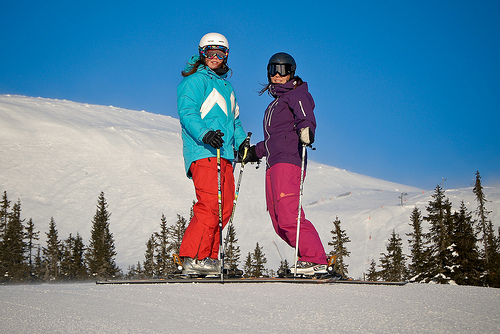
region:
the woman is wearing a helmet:
[199, 32, 228, 49]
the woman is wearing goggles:
[202, 45, 225, 59]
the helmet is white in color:
[197, 30, 225, 48]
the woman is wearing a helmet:
[266, 51, 293, 74]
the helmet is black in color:
[265, 51, 297, 78]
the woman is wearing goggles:
[266, 62, 291, 75]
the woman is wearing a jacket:
[250, 82, 315, 166]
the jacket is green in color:
[173, 65, 243, 176]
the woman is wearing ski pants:
[184, 150, 238, 266]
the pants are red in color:
[180, 155, 235, 260]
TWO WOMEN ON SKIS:
[171, 29, 342, 283]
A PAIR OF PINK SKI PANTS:
[263, 160, 331, 268]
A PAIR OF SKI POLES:
[211, 125, 256, 285]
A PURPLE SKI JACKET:
[250, 80, 319, 170]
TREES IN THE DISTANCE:
[334, 167, 498, 283]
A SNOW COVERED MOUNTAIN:
[4, 82, 178, 209]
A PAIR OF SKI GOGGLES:
[263, 60, 295, 80]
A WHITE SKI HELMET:
[194, 28, 234, 51]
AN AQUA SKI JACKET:
[174, 62, 253, 180]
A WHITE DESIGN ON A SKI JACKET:
[196, 86, 241, 123]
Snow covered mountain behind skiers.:
[11, 63, 495, 286]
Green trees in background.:
[6, 178, 497, 300]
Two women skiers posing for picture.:
[121, 10, 388, 301]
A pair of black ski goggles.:
[259, 48, 302, 89]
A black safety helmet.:
[256, 51, 313, 97]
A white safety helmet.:
[193, 28, 239, 76]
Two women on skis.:
[164, 16, 360, 293]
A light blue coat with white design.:
[173, 65, 250, 165]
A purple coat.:
[251, 79, 318, 168]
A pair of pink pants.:
[256, 155, 343, 276]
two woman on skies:
[85, 7, 392, 332]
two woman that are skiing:
[97, 4, 448, 330]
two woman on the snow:
[112, 30, 422, 311]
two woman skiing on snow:
[117, 32, 479, 327]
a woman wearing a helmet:
[142, 12, 243, 234]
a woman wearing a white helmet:
[162, 25, 252, 280]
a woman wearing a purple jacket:
[246, 44, 328, 279]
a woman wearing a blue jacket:
[158, 16, 245, 236]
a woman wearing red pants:
[162, 28, 248, 289]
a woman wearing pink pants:
[260, 21, 324, 283]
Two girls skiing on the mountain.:
[110, 7, 412, 330]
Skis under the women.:
[78, 205, 375, 295]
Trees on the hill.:
[41, 189, 195, 317]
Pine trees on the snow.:
[74, 167, 229, 287]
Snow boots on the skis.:
[163, 219, 396, 328]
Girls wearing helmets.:
[165, 18, 322, 119]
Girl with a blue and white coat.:
[136, 13, 261, 182]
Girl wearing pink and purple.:
[248, 38, 344, 294]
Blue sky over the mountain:
[348, 42, 497, 164]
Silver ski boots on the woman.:
[141, 228, 231, 310]